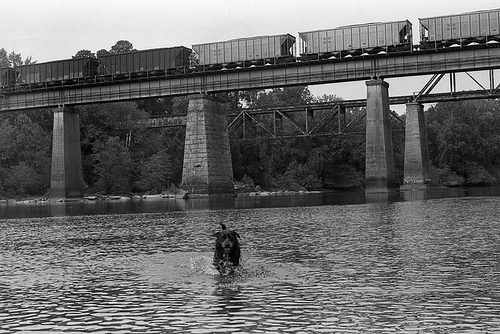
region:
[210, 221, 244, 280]
A dog moving through the water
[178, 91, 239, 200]
A stack stoned pillar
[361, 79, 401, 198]
A concrete support pillar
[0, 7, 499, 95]
A train on a bridge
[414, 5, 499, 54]
A single train car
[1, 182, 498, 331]
A river under a bridge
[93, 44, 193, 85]
A black train car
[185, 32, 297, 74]
A silver train car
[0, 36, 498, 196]
A wooded hillside by the river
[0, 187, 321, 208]
A rocky beach on the river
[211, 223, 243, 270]
A dark swimming dog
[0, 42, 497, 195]
A high bridge across the lake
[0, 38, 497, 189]
Thick vegetation on the edge of the lake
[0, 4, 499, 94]
A cargo train on track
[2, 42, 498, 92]
The train tracks built on a bridge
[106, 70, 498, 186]
The bridge on the right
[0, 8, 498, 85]
The six chain cabs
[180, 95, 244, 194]
The thick concrete beam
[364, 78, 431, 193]
The adjacent concrete beams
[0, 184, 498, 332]
The extensive lake water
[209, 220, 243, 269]
a dog is running in the water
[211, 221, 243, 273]
the dog is wet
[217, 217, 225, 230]
the dog's tail is in the air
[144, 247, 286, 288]
water is splashing around the dog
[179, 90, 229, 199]
the bridge support is brick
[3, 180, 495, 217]
the water is calm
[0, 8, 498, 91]
a train is on the track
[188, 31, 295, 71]
a train car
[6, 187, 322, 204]
rocks on the shore of the water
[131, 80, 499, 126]
train track is empty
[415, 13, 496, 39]
train on a track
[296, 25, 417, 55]
train on a track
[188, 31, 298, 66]
train on a track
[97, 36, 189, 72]
train on a track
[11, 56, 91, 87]
train on a track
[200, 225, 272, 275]
dog in a lake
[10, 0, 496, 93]
train cars on a bridge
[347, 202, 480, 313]
lake near a bridge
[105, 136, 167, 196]
tree near a lake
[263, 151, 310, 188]
tree near a lake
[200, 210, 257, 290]
a dog in the water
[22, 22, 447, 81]
cargo containers on the bridge